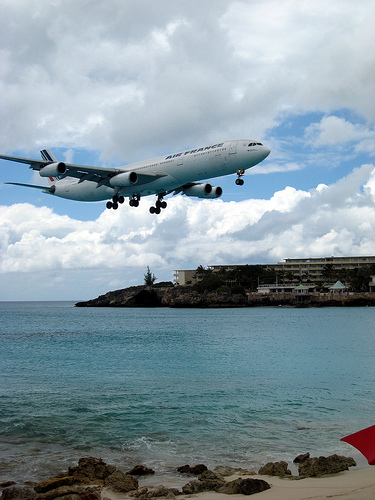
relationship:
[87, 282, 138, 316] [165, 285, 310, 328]
rocks on shore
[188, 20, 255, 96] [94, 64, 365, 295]
cloud in sky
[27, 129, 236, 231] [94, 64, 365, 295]
airplane in sky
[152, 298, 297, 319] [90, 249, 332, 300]
ledge of land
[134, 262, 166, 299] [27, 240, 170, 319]
tree at edge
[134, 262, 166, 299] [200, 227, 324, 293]
tree by building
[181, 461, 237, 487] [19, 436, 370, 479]
stone on beach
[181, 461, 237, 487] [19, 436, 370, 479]
stone at beach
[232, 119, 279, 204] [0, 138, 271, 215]
nose of airplane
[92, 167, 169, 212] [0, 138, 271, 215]
engine on airplane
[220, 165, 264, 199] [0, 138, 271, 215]
landing gear of airplane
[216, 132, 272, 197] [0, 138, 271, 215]
door of airplane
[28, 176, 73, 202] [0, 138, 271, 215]
tail of airplane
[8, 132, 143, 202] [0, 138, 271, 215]
wing of airplane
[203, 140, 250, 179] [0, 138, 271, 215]
writing on airplane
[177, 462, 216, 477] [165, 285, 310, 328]
rock on shore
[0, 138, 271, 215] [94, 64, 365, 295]
airplane in sky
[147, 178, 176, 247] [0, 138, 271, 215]
wheels on airplane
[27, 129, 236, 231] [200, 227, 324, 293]
airplane over building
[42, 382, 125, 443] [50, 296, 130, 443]
wave in ocean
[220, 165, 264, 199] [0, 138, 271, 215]
landing gear on airplane